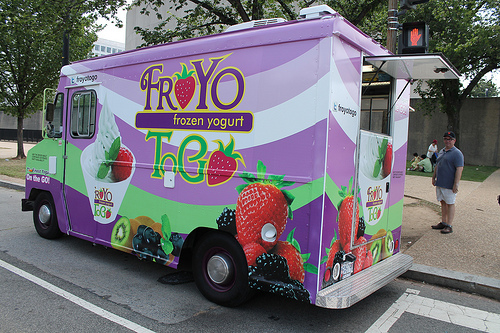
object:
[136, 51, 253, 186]
logo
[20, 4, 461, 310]
truck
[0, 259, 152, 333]
line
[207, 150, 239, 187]
strawberry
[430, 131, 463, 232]
man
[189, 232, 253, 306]
back tire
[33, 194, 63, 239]
front tire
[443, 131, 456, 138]
hat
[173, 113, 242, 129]
writing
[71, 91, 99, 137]
window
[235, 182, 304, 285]
strawberries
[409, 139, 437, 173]
family group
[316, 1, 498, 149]
tree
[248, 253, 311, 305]
blackberries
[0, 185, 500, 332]
road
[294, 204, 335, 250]
shades of purple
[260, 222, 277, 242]
gas filler cap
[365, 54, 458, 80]
overhead access door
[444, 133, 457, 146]
head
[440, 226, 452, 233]
left foot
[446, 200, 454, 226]
leg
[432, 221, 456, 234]
feet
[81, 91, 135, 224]
froyo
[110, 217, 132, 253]
kiwi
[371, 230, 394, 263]
kiwis